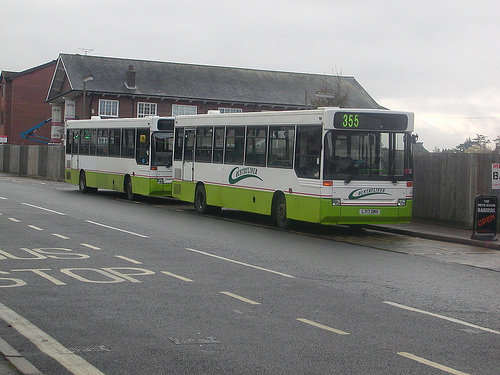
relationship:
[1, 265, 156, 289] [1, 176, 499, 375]
word on top of street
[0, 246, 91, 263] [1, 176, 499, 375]
word on top of street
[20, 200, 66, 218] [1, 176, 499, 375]
line on top of street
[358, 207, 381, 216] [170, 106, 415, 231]
license plate on front of bus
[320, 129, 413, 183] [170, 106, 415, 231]
windshield on front of bus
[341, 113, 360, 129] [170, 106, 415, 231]
number on front of bus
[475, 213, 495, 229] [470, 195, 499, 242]
word on top of sign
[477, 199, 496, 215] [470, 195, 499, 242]
word on top of sign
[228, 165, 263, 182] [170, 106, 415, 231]
writing on side of bus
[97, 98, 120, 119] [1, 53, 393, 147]
window on building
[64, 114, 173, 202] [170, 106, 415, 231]
bus parked in back of bus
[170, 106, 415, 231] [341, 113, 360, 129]
bus has number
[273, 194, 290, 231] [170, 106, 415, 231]
right wheel on front of bus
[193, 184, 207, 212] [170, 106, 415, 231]
right tire on rear of bus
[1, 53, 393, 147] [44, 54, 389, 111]
building has roof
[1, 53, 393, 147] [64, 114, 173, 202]
building in back of bus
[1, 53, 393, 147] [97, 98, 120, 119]
building has window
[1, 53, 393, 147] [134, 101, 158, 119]
building has window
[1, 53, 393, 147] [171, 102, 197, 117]
building has window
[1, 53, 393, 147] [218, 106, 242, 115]
building has window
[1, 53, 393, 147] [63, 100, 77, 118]
building has window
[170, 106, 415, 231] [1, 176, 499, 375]
bus parked on street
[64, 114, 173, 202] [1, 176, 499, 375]
bus parked on street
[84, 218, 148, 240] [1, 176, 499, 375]
line on top of street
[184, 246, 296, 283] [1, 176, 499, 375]
line on top of street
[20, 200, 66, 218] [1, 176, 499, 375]
line on street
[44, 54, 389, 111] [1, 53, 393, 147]
roof on top of building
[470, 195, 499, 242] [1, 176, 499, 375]
sign on side of street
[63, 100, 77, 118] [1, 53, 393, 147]
window on side of building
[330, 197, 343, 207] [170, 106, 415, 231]
light on front of bus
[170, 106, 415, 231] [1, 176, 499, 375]
bus on side of street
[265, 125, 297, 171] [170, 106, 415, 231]
window on side of bus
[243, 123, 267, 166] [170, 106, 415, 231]
window on side of bus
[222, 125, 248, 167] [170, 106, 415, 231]
window on side of bus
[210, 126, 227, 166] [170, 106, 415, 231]
window on side of bus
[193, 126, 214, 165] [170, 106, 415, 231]
window on side of bus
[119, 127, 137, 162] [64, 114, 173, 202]
window on side of bus